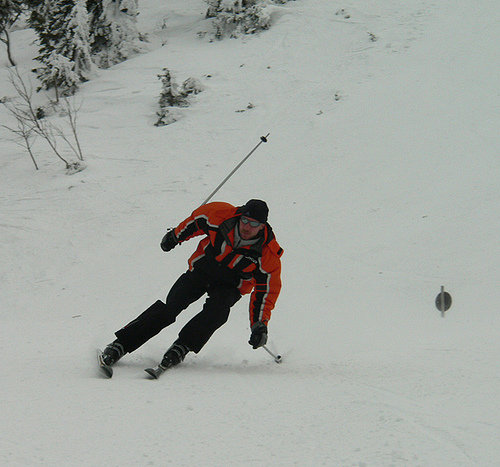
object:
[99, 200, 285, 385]
man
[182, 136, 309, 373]
poles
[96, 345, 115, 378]
skis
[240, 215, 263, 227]
glasses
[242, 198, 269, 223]
hat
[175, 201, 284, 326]
jacket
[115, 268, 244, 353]
pants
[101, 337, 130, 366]
boots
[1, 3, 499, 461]
snow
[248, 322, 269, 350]
gloves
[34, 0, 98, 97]
trees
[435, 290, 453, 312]
marker